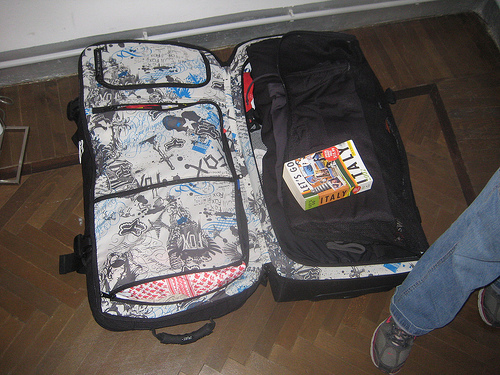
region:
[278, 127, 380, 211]
the book is on the suitcase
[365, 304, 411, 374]
the shoe is black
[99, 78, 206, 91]
the zipper is black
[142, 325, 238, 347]
the suitcase has a handle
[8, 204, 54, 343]
the floor is brown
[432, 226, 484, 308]
the jeans are blue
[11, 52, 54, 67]
the pipe is running along the wall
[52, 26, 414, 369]
the suitcase is black and white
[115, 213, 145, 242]
the fox is a logo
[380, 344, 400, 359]
the logo is on the top of the sneaker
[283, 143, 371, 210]
A book on the bag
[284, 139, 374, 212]
The book is about Italy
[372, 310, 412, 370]
A shoe on the right foot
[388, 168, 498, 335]
The person is wearing pants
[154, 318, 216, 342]
A handle on the bag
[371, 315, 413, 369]
The shoe is black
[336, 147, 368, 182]
The title of the book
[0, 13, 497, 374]
The ground below the bag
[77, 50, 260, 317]
A design on the bag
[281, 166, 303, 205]
Pages of the book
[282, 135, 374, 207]
a book is on the suitcase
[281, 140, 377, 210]
the book is made of paper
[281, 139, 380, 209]
the book is thick in width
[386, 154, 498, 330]
a section of jean is on the right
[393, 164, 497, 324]
the jeans are blue in color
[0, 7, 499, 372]
the floor is made of wood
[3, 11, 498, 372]
the wood is brown in color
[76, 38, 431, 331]
the suitcase is in an open position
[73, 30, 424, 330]
the suitcase is laying on the floor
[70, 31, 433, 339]
the suitcase is spread open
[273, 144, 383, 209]
The book is on the luggage.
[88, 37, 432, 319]
The luggage is open.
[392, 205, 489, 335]
The man is wearing jeans.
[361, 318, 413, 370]
His shoes are gray.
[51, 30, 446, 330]
The luggage is on the floor.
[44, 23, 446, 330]
He is standing next to the luggage.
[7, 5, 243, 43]
The wall is white.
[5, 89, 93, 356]
The floor is brown.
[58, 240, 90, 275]
The handle is black.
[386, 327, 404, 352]
The laces are gray.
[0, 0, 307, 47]
surface of white wall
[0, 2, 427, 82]
pole attached to wall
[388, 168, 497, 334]
leg of blue jean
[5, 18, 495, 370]
pattern in wood floor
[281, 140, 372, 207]
cover of paper book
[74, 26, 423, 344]
inside of open suitcase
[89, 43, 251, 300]
pattern inside of suitcase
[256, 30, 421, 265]
black nylon of suitcase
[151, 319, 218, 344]
handle on top of suitcase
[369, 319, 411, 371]
top of gray sneaker